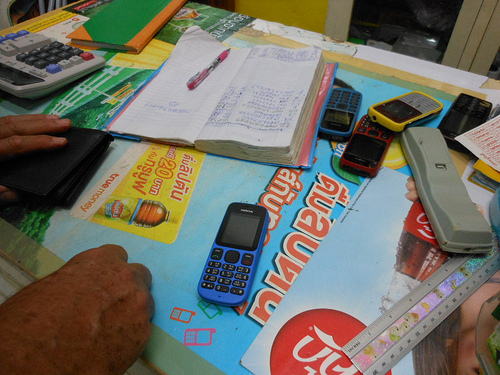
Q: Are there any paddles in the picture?
A: No, there are no paddles.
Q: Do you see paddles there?
A: No, there are no paddles.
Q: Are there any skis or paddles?
A: No, there are no paddles or skis.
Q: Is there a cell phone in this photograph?
A: Yes, there is a cell phone.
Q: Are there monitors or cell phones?
A: Yes, there is a cell phone.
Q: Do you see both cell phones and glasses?
A: No, there is a cell phone but no glasses.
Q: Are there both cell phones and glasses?
A: No, there is a cell phone but no glasses.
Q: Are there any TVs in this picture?
A: No, there are no tvs.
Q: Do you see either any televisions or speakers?
A: No, there are no televisions or speakers.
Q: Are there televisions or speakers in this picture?
A: No, there are no televisions or speakers.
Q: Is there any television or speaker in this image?
A: No, there are no televisions or speakers.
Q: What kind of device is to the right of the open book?
A: The device is a cell phone.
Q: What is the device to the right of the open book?
A: The device is a cell phone.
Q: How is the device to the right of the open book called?
A: The device is a cell phone.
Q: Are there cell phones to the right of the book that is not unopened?
A: Yes, there is a cell phone to the right of the book.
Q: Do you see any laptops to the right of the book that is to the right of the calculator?
A: No, there is a cell phone to the right of the book.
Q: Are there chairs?
A: No, there are no chairs.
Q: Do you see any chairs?
A: No, there are no chairs.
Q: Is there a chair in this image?
A: No, there are no chairs.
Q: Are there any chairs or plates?
A: No, there are no chairs or plates.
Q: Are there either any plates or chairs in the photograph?
A: No, there are no chairs or plates.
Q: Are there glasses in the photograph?
A: No, there are no glasses.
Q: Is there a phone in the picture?
A: Yes, there is a phone.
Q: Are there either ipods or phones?
A: Yes, there is a phone.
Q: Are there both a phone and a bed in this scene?
A: No, there is a phone but no beds.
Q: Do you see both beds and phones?
A: No, there is a phone but no beds.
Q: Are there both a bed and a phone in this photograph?
A: No, there is a phone but no beds.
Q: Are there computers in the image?
A: No, there are no computers.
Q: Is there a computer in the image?
A: No, there are no computers.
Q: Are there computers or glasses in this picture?
A: No, there are no computers or glasses.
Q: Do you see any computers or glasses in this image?
A: No, there are no computers or glasses.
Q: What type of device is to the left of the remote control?
A: The device is a phone.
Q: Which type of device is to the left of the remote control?
A: The device is a phone.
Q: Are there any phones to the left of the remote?
A: Yes, there is a phone to the left of the remote.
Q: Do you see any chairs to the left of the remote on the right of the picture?
A: No, there is a phone to the left of the remote control.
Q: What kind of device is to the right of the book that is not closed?
A: The device is a phone.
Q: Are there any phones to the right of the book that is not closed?
A: Yes, there is a phone to the right of the book.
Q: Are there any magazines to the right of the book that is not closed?
A: No, there is a phone to the right of the book.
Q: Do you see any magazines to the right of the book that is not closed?
A: No, there is a phone to the right of the book.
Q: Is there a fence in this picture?
A: No, there are no fences.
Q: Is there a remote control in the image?
A: Yes, there is a remote control.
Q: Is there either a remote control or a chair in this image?
A: Yes, there is a remote control.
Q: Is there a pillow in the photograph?
A: No, there are no pillows.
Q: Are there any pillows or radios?
A: No, there are no pillows or radios.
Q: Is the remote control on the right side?
A: Yes, the remote control is on the right of the image.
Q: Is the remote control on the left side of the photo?
A: No, the remote control is on the right of the image.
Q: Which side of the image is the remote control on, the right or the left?
A: The remote control is on the right of the image.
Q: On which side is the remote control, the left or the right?
A: The remote control is on the right of the image.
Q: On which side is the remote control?
A: The remote control is on the right of the image.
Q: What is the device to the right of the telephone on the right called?
A: The device is a remote control.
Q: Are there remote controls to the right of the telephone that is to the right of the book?
A: Yes, there is a remote control to the right of the telephone.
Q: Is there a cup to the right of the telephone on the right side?
A: No, there is a remote control to the right of the phone.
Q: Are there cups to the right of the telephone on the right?
A: No, there is a remote control to the right of the phone.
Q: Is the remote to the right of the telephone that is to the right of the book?
A: Yes, the remote is to the right of the telephone.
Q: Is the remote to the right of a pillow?
A: No, the remote is to the right of the telephone.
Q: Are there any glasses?
A: No, there are no glasses.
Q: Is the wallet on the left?
A: Yes, the wallet is on the left of the image.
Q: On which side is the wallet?
A: The wallet is on the left of the image.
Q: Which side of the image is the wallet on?
A: The wallet is on the left of the image.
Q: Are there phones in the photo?
A: Yes, there is a phone.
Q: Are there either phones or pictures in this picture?
A: Yes, there is a phone.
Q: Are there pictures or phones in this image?
A: Yes, there is a phone.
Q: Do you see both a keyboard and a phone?
A: No, there is a phone but no keyboards.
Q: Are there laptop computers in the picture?
A: No, there are no laptop computers.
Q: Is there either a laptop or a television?
A: No, there are no laptops or televisions.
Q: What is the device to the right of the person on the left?
A: The device is a phone.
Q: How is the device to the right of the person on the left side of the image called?
A: The device is a phone.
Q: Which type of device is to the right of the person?
A: The device is a phone.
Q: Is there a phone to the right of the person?
A: Yes, there is a phone to the right of the person.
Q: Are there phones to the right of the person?
A: Yes, there is a phone to the right of the person.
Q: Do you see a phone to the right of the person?
A: Yes, there is a phone to the right of the person.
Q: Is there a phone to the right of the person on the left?
A: Yes, there is a phone to the right of the person.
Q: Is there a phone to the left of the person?
A: No, the phone is to the right of the person.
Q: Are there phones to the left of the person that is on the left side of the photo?
A: No, the phone is to the right of the person.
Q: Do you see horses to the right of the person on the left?
A: No, there is a phone to the right of the person.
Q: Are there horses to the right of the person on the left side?
A: No, there is a phone to the right of the person.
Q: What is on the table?
A: The telephone is on the table.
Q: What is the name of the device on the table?
A: The device is a phone.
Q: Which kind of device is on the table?
A: The device is a phone.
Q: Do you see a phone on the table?
A: Yes, there is a phone on the table.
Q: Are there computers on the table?
A: No, there is a phone on the table.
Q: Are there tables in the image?
A: Yes, there is a table.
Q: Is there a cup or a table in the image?
A: Yes, there is a table.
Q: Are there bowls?
A: No, there are no bowls.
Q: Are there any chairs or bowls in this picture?
A: No, there are no bowls or chairs.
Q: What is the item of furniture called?
A: The piece of furniture is a table.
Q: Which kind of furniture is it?
A: The piece of furniture is a table.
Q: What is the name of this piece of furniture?
A: That is a table.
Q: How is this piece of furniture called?
A: That is a table.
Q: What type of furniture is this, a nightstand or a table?
A: That is a table.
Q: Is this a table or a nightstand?
A: This is a table.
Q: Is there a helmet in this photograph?
A: No, there are no helmets.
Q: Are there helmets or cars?
A: No, there are no helmets or cars.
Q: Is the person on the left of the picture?
A: Yes, the person is on the left of the image.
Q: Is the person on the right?
A: No, the person is on the left of the image.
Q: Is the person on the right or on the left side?
A: The person is on the left of the image.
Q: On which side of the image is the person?
A: The person is on the left of the image.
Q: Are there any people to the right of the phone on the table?
A: No, the person is to the left of the phone.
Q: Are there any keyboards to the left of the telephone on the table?
A: No, there is a person to the left of the phone.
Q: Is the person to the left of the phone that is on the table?
A: Yes, the person is to the left of the phone.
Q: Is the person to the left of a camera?
A: No, the person is to the left of the phone.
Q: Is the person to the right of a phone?
A: No, the person is to the left of a phone.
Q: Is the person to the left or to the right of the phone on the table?
A: The person is to the left of the phone.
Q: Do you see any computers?
A: No, there are no computers.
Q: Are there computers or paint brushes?
A: No, there are no computers or paint brushes.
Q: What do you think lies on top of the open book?
A: The pen lies on top of the book.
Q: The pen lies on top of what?
A: The pen lies on top of the book.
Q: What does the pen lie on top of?
A: The pen lies on top of the book.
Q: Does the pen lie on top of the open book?
A: Yes, the pen lies on top of the book.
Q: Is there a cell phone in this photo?
A: Yes, there are cell phones.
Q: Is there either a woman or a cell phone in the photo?
A: Yes, there are cell phones.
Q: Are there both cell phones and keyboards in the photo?
A: No, there are cell phones but no keyboards.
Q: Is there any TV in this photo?
A: No, there are no televisions.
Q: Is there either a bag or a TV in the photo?
A: No, there are no televisions or bags.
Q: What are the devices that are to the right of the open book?
A: The devices are cell phones.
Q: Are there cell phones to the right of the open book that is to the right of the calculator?
A: Yes, there are cell phones to the right of the book.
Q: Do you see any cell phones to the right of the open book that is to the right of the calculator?
A: Yes, there are cell phones to the right of the book.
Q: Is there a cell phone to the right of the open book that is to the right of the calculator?
A: Yes, there are cell phones to the right of the book.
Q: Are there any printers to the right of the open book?
A: No, there are cell phones to the right of the book.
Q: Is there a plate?
A: No, there are no plates.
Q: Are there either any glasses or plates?
A: No, there are no plates or glasses.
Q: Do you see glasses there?
A: No, there are no glasses.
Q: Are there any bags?
A: No, there are no bags.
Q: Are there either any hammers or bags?
A: No, there are no bags or hammers.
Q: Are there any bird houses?
A: No, there are no bird houses.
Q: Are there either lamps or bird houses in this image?
A: No, there are no bird houses or lamps.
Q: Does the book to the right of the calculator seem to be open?
A: Yes, the book is open.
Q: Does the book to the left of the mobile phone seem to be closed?
A: No, the book is open.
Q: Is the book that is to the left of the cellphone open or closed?
A: The book is open.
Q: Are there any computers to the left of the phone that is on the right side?
A: No, there is a book to the left of the telephone.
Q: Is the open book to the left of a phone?
A: Yes, the book is to the left of a phone.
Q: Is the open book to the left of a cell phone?
A: Yes, the book is to the left of a cell phone.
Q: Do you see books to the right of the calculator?
A: Yes, there is a book to the right of the calculator.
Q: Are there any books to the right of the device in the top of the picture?
A: Yes, there is a book to the right of the calculator.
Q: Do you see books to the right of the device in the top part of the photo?
A: Yes, there is a book to the right of the calculator.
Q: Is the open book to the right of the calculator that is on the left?
A: Yes, the book is to the right of the calculator.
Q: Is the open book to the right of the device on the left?
A: Yes, the book is to the right of the calculator.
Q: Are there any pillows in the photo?
A: No, there are no pillows.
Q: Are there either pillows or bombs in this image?
A: No, there are no pillows or bombs.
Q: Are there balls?
A: No, there are no balls.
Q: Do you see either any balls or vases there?
A: No, there are no balls or vases.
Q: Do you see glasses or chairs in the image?
A: No, there are no glasses or chairs.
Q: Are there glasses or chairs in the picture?
A: No, there are no glasses or chairs.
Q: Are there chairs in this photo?
A: No, there are no chairs.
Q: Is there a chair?
A: No, there are no chairs.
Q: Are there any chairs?
A: No, there are no chairs.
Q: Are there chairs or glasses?
A: No, there are no chairs or glasses.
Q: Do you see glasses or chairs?
A: No, there are no chairs or glasses.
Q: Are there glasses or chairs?
A: No, there are no chairs or glasses.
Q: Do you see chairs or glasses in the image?
A: No, there are no chairs or glasses.